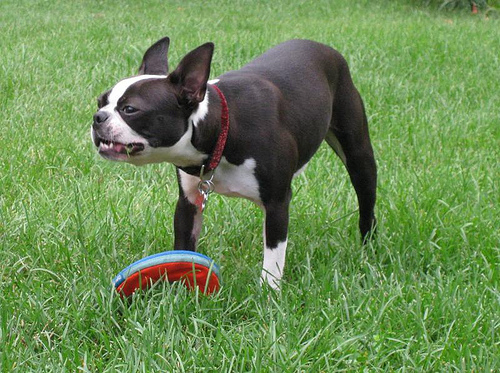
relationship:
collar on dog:
[188, 80, 235, 220] [84, 32, 409, 303]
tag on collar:
[193, 179, 222, 211] [188, 80, 235, 220]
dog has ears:
[84, 32, 409, 303] [135, 34, 219, 108]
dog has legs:
[84, 32, 409, 303] [162, 141, 398, 291]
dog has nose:
[84, 32, 409, 303] [86, 110, 112, 132]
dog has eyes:
[84, 32, 409, 303] [95, 96, 141, 118]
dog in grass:
[84, 32, 409, 303] [1, 1, 500, 372]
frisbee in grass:
[104, 247, 229, 314] [1, 1, 500, 372]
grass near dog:
[1, 1, 500, 372] [84, 32, 409, 303]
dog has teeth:
[84, 32, 409, 303] [95, 136, 120, 152]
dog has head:
[84, 32, 409, 303] [81, 35, 220, 185]